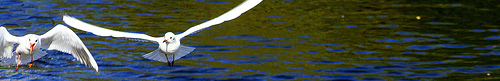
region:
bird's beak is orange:
[158, 34, 169, 44]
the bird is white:
[56, 0, 280, 64]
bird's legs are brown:
[164, 51, 183, 68]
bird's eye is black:
[170, 31, 177, 41]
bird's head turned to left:
[156, 25, 178, 49]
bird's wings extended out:
[54, 1, 304, 68]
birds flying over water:
[1, 1, 268, 71]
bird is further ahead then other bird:
[0, 16, 102, 79]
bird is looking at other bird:
[63, 2, 273, 69]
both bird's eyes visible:
[26, 32, 43, 46]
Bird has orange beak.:
[28, 43, 39, 49]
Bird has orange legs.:
[11, 53, 46, 59]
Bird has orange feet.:
[13, 63, 44, 69]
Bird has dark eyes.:
[26, 34, 52, 46]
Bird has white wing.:
[47, 26, 104, 73]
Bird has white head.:
[25, 35, 46, 41]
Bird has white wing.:
[5, 30, 20, 49]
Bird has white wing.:
[185, 2, 251, 56]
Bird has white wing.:
[77, 16, 144, 33]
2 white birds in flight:
[6, 4, 471, 75]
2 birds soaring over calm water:
[8, 4, 428, 77]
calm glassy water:
[267, 8, 359, 68]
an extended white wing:
[172, 3, 288, 57]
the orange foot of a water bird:
[15, 53, 24, 69]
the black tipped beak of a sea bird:
[158, 38, 168, 48]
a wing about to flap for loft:
[36, 17, 106, 73]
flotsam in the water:
[411, 8, 431, 32]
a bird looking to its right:
[145, 18, 191, 65]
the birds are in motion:
[0, 0, 264, 73]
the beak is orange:
[154, 35, 171, 46]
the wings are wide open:
[51, 0, 278, 74]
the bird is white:
[47, 0, 280, 73]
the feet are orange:
[0, 54, 42, 73]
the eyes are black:
[17, 32, 44, 45]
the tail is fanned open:
[136, 38, 211, 71]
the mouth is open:
[20, 34, 42, 56]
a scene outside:
[3, 6, 434, 78]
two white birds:
[4, 1, 371, 79]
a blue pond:
[9, 6, 495, 73]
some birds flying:
[4, 3, 353, 74]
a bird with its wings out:
[51, 3, 267, 72]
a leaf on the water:
[405, 11, 427, 26]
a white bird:
[0, 15, 102, 77]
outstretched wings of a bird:
[60, 0, 268, 40]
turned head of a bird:
[157, 31, 176, 46]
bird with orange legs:
[0, 19, 102, 77]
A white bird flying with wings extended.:
[62, 1, 264, 66]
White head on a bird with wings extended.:
[162, 31, 175, 42]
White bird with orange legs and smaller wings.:
[1, 24, 101, 71]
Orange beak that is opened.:
[28, 41, 37, 52]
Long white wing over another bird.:
[63, 14, 157, 44]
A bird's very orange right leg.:
[14, 50, 21, 70]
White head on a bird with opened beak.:
[26, 35, 38, 48]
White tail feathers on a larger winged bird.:
[143, 41, 195, 62]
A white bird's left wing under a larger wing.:
[42, 24, 99, 72]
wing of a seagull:
[63, 10, 155, 57]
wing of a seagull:
[176, 0, 271, 42]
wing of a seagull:
[36, 19, 110, 79]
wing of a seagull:
[0, 22, 21, 64]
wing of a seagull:
[39, 20, 100, 74]